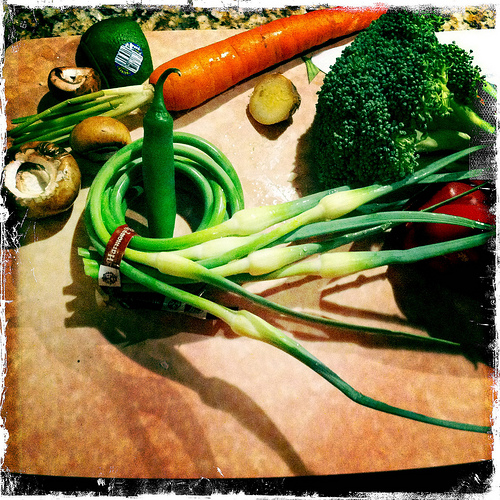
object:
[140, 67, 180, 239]
pepper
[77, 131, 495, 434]
hard neck garlic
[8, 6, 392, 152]
carrot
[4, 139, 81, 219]
mushroom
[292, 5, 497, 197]
broccoli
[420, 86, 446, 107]
floret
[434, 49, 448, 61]
floret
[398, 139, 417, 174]
floret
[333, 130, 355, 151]
floret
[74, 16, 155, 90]
lime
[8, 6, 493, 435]
ingredients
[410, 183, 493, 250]
apple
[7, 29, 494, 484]
cutting board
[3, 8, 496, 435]
vegetables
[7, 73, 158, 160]
top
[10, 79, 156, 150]
stem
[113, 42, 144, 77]
sticker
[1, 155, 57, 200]
underside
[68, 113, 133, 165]
mushroom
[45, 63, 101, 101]
mushroom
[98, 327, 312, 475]
shadow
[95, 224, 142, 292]
twist tie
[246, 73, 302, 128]
potato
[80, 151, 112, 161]
side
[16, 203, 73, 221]
back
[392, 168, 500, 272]
pepper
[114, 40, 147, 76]
barcode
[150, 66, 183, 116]
stem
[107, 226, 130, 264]
'harmony'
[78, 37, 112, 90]
seam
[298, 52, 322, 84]
leaf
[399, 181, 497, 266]
mystery vegetable ii